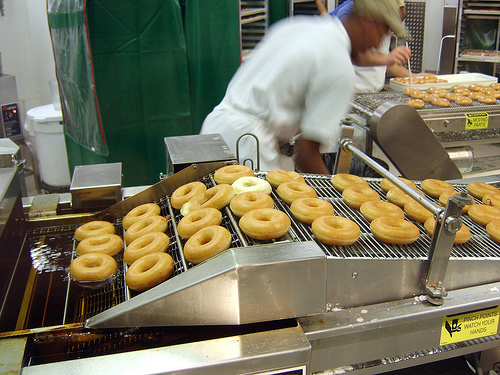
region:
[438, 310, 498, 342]
yellow label on the side of the machine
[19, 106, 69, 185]
white container in the back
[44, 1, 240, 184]
green plastic tent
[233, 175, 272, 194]
white single donut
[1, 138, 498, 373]
silver machine with donuts on it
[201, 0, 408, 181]
man overseeing the machine with the donuts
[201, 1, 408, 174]
man with brown hat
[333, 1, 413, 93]
man checking donuts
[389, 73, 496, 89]
donuts in a white container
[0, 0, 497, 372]
inside of a factory for making donuts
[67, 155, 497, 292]
donuts on a conveyor belt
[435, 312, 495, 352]
black and yellow sticker in the foreground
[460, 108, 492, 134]
yellow and black sticker in the background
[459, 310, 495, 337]
black text on yellow background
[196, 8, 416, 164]
man working behind the conveyor blet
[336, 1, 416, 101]
man glazing the donuts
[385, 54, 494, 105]
donuts being glazed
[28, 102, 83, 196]
white trashcan with white lid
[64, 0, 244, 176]
green curtain behind the men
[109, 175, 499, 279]
conveyor belt donuts are on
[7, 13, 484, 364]
photograph taken at a donut bakery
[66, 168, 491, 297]
yellow donuts on conveyor belt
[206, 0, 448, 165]
two people cooking donuts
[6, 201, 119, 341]
oil for donuts to cook in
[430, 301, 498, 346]
yellow safety sign on conveor belt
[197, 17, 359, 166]
baker dressed in all white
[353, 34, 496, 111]
person putting glaze on donuts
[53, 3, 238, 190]
green plastic covering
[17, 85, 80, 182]
white plastic container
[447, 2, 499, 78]
racks for cooked donuts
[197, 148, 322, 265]
Group of doughnuts on a belt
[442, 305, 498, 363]
Sticker on side of belt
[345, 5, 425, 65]
Hat on the man's head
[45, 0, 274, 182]
Green cover for the shelves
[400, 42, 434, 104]
Man holding a spoon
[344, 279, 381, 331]
Glaze on the machine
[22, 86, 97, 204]
Container by the wall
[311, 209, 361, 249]
glazed donut on a conveyer belt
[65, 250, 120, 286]
glazed donut on a conveyer belt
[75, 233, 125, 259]
glazed donut on a conveyer belt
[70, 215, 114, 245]
glazed donut on a conveyer belt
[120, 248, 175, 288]
glazed donut on a conveyer belt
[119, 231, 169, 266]
glazed donut on a conveyer belt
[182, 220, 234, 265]
glazed donut on a conveyer belt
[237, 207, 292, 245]
glazed donut on a conveyer belt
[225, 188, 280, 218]
glazed donut on a conveyer belt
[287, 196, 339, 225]
glazed donut on a conveyer belt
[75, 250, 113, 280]
a doughnut is on the converyor belt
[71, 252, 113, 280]
the doughnut is golden brown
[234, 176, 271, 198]
the doughnut is white in color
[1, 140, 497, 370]
the machine is made of metal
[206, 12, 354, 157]
a man is wearing a white oufit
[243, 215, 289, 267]
a donut on the belt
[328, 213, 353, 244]
a donut on the belt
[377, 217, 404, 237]
a donut on the belt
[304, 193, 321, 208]
a donut on the belt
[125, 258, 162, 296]
a donut on the belt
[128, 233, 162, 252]
a donut on the belt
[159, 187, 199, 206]
a donut on the belt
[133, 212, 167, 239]
a donut on the belt